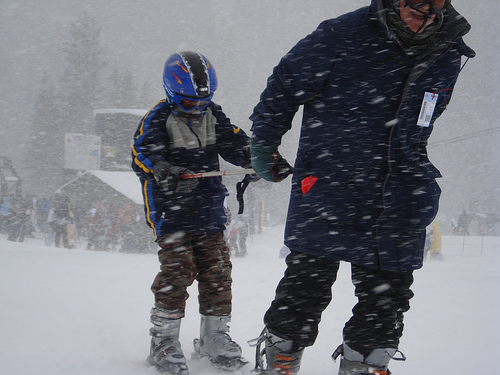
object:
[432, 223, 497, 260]
fence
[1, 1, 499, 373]
snow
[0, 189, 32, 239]
people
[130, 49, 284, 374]
boy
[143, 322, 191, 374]
feet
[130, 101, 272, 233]
cloth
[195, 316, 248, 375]
snow ski's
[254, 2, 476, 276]
jacket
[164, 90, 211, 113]
goggles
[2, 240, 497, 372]
field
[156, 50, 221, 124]
helmet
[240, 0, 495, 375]
man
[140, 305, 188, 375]
skis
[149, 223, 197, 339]
leg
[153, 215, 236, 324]
pants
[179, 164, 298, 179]
ski pole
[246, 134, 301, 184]
glove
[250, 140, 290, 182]
hand